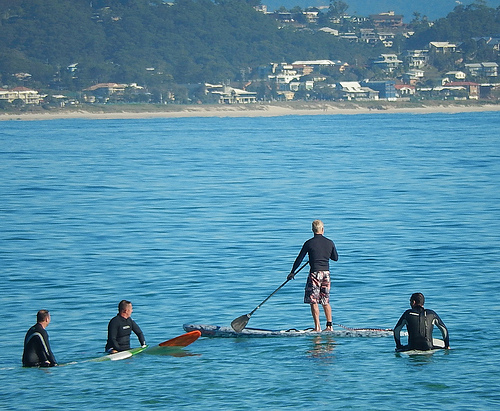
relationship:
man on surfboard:
[296, 204, 339, 327] [218, 325, 393, 341]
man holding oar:
[296, 204, 339, 327] [229, 259, 311, 332]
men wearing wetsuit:
[14, 303, 149, 359] [95, 322, 140, 350]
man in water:
[21, 308, 67, 382] [18, 364, 229, 392]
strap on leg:
[327, 320, 339, 329] [318, 298, 336, 336]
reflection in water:
[305, 340, 341, 363] [18, 364, 229, 392]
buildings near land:
[186, 56, 483, 103] [6, 95, 500, 122]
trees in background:
[11, 11, 283, 77] [8, 7, 483, 87]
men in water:
[14, 303, 149, 359] [18, 364, 229, 392]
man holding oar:
[296, 204, 339, 327] [232, 292, 272, 337]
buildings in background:
[186, 56, 483, 103] [8, 7, 483, 87]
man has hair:
[296, 204, 339, 327] [306, 221, 334, 232]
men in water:
[14, 303, 149, 359] [0, 110, 500, 411]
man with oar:
[296, 204, 339, 327] [229, 259, 311, 332]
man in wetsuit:
[21, 308, 67, 382] [95, 322, 140, 350]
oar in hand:
[229, 259, 311, 332] [281, 272, 298, 282]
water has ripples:
[0, 110, 500, 411] [144, 174, 313, 219]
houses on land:
[95, 75, 253, 108] [15, 102, 278, 115]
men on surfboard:
[14, 303, 149, 359] [162, 327, 198, 353]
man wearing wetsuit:
[21, 308, 67, 382] [95, 322, 140, 350]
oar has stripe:
[229, 259, 311, 332] [257, 303, 263, 313]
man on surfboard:
[21, 308, 67, 382] [85, 345, 159, 371]